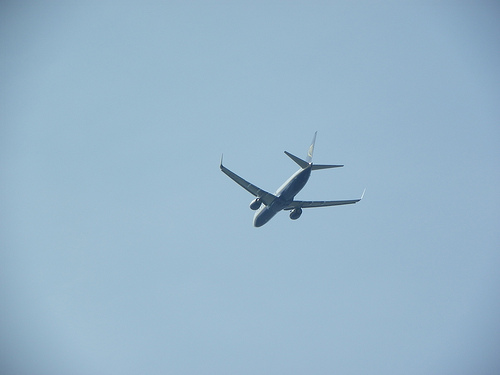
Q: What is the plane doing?
A: Flying.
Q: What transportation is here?
A: Plane.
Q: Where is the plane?
A: Sky.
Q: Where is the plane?
A: Sky.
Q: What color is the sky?
A: Blue.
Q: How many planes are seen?
A: 1.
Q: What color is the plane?
A: White.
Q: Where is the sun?
A: Out of frame.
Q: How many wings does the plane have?
A: 2.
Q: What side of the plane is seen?
A: Underside.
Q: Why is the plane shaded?
A: The sun is above it.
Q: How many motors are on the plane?
A: 2.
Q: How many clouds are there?
A: None.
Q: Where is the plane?
A: In the air.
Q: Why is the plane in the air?
A: Flying.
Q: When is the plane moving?
A: Now.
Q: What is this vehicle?
A: Plane.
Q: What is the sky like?
A: Clear.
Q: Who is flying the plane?
A: Pilot.